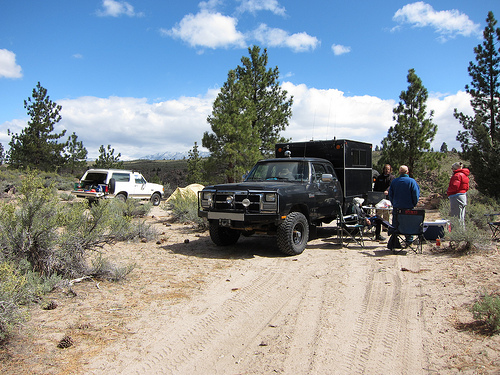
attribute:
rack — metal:
[197, 187, 284, 221]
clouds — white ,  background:
[18, 90, 476, 156]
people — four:
[352, 155, 479, 251]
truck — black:
[194, 127, 388, 257]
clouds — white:
[1, 1, 499, 148]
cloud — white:
[5, 83, 476, 168]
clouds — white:
[303, 86, 372, 134]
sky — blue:
[1, 4, 498, 154]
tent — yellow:
[149, 179, 216, 218]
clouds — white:
[161, 0, 353, 60]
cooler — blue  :
[421, 218, 448, 235]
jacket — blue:
[387, 176, 419, 211]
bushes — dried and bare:
[14, 193, 128, 279]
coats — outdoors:
[448, 169, 475, 190]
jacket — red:
[443, 165, 473, 197]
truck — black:
[184, 117, 415, 267]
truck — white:
[69, 163, 169, 210]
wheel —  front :
[274, 209, 311, 256]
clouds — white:
[109, 57, 201, 137]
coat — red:
[441, 169, 481, 219]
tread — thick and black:
[270, 223, 317, 294]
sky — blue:
[0, 49, 480, 89]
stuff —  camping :
[65, 156, 166, 214]